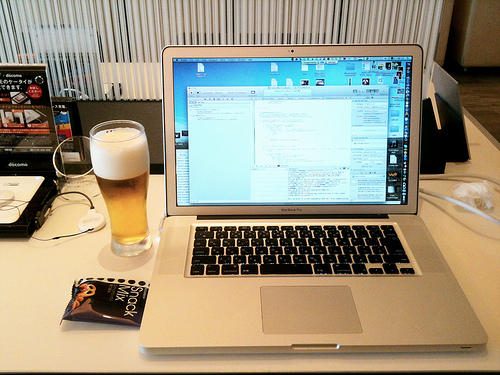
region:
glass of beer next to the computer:
[77, 115, 158, 256]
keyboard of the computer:
[183, 221, 418, 282]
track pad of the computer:
[256, 281, 367, 339]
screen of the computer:
[170, 55, 410, 206]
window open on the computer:
[187, 88, 384, 201]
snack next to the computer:
[57, 275, 149, 332]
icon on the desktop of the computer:
[265, 59, 281, 74]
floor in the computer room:
[461, 73, 496, 126]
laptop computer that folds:
[141, 40, 487, 351]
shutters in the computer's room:
[3, 6, 433, 42]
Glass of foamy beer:
[85, 118, 155, 260]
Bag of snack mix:
[56, 274, 151, 330]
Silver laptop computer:
[135, 42, 490, 356]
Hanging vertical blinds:
[0, 0, 444, 101]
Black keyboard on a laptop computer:
[182, 223, 417, 276]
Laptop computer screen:
[171, 57, 408, 205]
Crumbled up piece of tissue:
[450, 180, 497, 214]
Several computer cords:
[32, 174, 109, 246]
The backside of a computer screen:
[429, 60, 472, 168]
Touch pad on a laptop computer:
[256, 283, 363, 336]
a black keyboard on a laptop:
[192, 222, 414, 278]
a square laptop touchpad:
[259, 284, 363, 336]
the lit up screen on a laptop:
[171, 55, 412, 208]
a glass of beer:
[90, 118, 151, 257]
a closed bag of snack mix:
[61, 276, 153, 326]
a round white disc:
[79, 205, 105, 232]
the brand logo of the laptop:
[279, 204, 306, 214]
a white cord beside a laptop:
[418, 185, 498, 230]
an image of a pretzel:
[82, 285, 96, 297]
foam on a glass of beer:
[92, 127, 152, 178]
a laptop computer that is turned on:
[146, 42, 487, 356]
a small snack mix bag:
[60, 270, 146, 334]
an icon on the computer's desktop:
[264, 60, 279, 73]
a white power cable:
[416, 171, 498, 236]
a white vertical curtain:
[1, 1, 431, 98]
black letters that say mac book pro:
[278, 206, 303, 212]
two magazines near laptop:
[0, 61, 86, 166]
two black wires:
[31, 189, 96, 246]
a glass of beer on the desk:
[87, 121, 152, 256]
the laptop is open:
[141, 44, 481, 354]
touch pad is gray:
[255, 284, 362, 336]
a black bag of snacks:
[59, 277, 146, 324]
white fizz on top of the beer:
[88, 126, 148, 180]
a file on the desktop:
[386, 154, 399, 166]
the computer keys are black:
[182, 222, 415, 277]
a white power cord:
[417, 174, 499, 226]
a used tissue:
[455, 182, 494, 208]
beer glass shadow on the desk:
[98, 244, 152, 273]